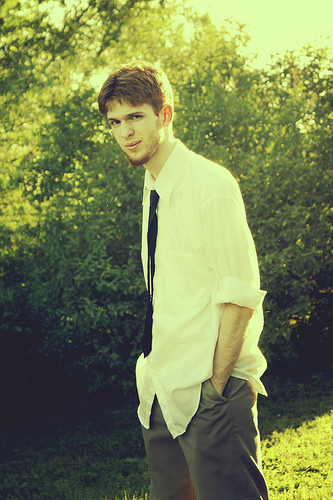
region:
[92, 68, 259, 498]
handsome guy standing in a garden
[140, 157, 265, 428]
white t-shirt of a tall handsome boy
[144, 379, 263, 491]
grey pants of a handsome guy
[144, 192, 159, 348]
black tie in a white t-shirt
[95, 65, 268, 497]
redhead guy standing with hands in his pockets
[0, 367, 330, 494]
green grass in the field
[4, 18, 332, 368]
big green bushes behind the guy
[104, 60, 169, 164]
head of a guy standing with white t-shirt and grey pants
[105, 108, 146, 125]
two small black eyes with an intense look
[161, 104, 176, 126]
small left ear of a handsome guy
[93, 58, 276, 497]
Man with orange hair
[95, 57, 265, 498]
Man with orange beard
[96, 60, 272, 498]
Man with white shirt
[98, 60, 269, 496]
Man with black tie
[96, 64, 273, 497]
Man with grey pants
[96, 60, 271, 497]
Man with hands in pockets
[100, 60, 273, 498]
Man with untucked shirt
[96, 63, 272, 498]
Man standing out doors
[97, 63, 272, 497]
Man walking on grass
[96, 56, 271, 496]
Man with short hair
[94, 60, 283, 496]
the young man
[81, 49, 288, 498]
the young man wearing a shirt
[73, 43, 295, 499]
the young man wearing a tie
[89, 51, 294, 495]
the young man wearing pants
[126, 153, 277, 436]
the shirt is white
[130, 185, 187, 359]
the tie is black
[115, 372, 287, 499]
the pants are brown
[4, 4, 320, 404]
the trees behind the young man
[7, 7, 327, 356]
the trees with green leaves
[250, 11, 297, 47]
the sun is shining brightly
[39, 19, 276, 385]
a man standing up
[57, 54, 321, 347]
a man smiling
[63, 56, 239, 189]
a man that is smiling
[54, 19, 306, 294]
a man with a short beard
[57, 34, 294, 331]
a man wearing a shirt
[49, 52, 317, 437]
a man wearing a long shirt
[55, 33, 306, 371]
a man wearing a long sleeve shirt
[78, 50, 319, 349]
a man wearing tie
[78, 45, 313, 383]
a man wearing a black tie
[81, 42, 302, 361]
a man wearing a button down shirt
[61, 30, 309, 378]
a man in a white shirt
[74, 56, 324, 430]
a man wearing white shirt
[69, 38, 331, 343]
a man wearing long sleeve shirt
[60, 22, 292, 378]
a man wearing a white long sleeve shirt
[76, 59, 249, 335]
a man wearing a tie